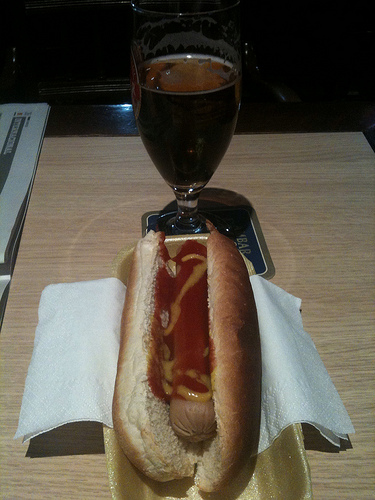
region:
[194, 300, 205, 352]
The ketchup is red.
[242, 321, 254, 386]
The hot dog bun is brown.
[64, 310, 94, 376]
The napkin is white.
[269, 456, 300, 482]
The container is yellow.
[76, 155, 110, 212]
The table is wood.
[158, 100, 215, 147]
The drink is brown.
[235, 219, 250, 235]
The coaster is blue.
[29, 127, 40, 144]
The newspaper is white.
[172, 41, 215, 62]
The glass is clear.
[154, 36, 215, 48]
There is foam in the glass.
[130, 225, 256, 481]
HOT DOG AND ROLL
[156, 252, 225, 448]
KETCHUP, MUSTARD AND ONIONS ARE ON THE HOTDOG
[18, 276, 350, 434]
NAPKIN IS UNDER THE HOT DOG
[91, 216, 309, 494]
HOT DOG IS IN A YELLOW TRAY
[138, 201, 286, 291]
BEVERAGE IS ON A COASTER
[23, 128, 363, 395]
ITEMS ARE ON A TABLE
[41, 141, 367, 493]
TABLE IS OF A TAN COLOR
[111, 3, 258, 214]
BEVERAGE IN GLASS IS YELLOW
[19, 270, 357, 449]
NAPKIN IS WHITE IN COLOR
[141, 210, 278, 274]
COASTER IS SQUARE SHAPED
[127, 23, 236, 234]
A glass of beer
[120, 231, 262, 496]
A hot dog in a bun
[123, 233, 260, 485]
A hot dog with ketchup and mustard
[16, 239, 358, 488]
A white napkin under a hot dog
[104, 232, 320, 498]
A hot dog in a Styrofoam container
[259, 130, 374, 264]
A table with wood grain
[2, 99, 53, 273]
The corner of a newspaper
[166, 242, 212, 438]
Ketchup and mustard on a frankfurter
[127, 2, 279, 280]
A glass on a drink coaster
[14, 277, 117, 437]
A white napkin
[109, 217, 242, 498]
hot dog in bun on table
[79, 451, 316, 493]
yellow styrafoam container around dog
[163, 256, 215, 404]
ketchup spread on hotdog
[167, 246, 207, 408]
melted cheese on hot dog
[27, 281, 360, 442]
white paper napkin under hot dog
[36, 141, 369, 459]
light wooden table underneath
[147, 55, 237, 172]
glass of ale next to food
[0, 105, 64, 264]
white magazine on left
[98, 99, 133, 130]
shiny metal object in background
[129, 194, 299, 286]
square coaster under glass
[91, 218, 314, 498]
a hot dog in a bowl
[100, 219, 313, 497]
a bun in a bowl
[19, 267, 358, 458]
a white napkin under a bun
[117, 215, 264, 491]
ketchup over a hot dog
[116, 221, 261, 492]
mustard over ketchup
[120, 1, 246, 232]
a cup of beer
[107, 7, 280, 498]
a cup of beer in front a hot dog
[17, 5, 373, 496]
a brown table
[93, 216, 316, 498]
a bun on a yellow cup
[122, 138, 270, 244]
the shadow of a cup